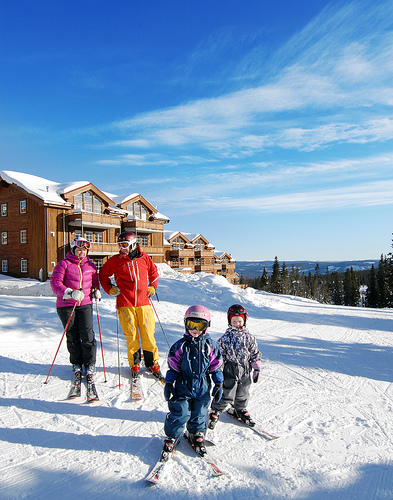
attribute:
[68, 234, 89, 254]
helmet — pink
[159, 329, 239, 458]
suit — blue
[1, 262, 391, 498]
snow — white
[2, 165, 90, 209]
snow — white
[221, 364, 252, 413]
pants — gray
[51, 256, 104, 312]
coat — pink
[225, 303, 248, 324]
helmet — red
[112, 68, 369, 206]
clouds — white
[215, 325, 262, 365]
jacket — red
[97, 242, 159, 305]
jacket — red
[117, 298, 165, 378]
snowpants — yellow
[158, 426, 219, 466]
boots — black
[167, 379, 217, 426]
pants — blue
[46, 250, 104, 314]
coat — pink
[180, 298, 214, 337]
helmet — pink